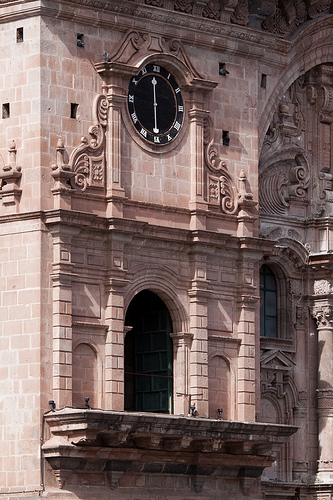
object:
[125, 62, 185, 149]
clock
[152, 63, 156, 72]
number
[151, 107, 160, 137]
hand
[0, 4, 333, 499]
building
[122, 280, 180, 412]
window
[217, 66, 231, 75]
bird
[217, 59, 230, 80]
hole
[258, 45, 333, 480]
arch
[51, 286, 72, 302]
brick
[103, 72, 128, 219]
column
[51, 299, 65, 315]
brick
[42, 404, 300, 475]
balcony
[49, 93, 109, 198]
carving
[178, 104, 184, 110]
number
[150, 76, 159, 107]
hand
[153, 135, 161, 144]
six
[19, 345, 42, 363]
brick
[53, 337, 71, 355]
brick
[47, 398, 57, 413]
light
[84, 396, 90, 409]
spotlight